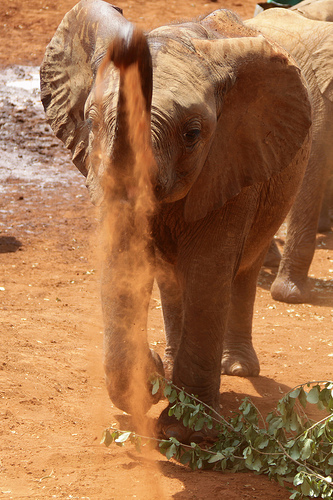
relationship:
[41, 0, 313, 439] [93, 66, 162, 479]
elephant picking up dirt cloud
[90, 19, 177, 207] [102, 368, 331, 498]
trunk picks up branches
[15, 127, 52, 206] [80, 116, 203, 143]
ground looking at eyes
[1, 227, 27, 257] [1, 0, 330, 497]
shadow on ground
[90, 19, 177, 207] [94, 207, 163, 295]
trunk full of dust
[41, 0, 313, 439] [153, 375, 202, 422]
elephant eating grass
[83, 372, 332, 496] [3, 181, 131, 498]
leaves on ground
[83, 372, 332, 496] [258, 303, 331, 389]
leaves on ground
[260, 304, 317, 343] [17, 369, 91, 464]
stones on ground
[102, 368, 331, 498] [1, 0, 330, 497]
branches on ground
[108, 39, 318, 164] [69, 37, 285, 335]
head of elephant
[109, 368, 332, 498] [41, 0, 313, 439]
shadow of elephant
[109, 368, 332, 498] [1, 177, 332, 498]
shadow on ground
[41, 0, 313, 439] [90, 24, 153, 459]
elephant playing with dust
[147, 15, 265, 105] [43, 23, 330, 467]
back of elephant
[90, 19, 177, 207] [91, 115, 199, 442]
trunk dropping soil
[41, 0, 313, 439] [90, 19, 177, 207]
elephant possesses trunk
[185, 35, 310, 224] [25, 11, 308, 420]
left ear of elephant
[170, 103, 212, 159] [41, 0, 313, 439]
eye of elephant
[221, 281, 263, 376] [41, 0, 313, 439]
leg of elephant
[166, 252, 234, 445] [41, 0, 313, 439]
leg of elephant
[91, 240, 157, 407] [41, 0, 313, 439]
leg of elephant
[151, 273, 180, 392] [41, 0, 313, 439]
leg of elephant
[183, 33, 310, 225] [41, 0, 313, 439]
ear of elephant